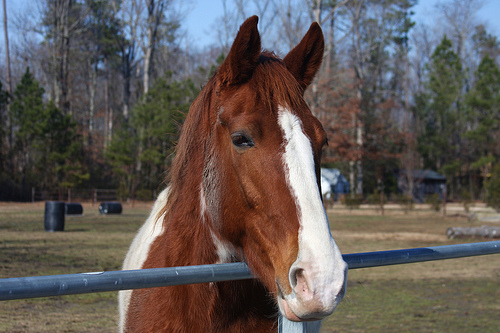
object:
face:
[214, 89, 343, 292]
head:
[199, 15, 349, 322]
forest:
[0, 0, 500, 207]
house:
[316, 167, 445, 203]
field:
[1, 171, 500, 329]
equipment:
[63, 202, 83, 215]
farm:
[0, 177, 500, 333]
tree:
[0, 60, 87, 202]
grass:
[31, 227, 500, 328]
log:
[448, 225, 499, 240]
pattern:
[277, 108, 332, 251]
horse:
[117, 14, 346, 333]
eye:
[229, 133, 254, 147]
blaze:
[256, 105, 333, 245]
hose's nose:
[287, 262, 349, 313]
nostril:
[288, 268, 304, 289]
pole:
[0, 238, 499, 302]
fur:
[163, 196, 198, 258]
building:
[321, 167, 342, 202]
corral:
[0, 239, 500, 333]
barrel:
[99, 201, 124, 215]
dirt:
[200, 136, 220, 239]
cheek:
[201, 122, 244, 245]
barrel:
[43, 199, 66, 233]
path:
[0, 207, 496, 330]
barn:
[395, 169, 447, 202]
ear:
[221, 14, 261, 85]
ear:
[281, 21, 325, 85]